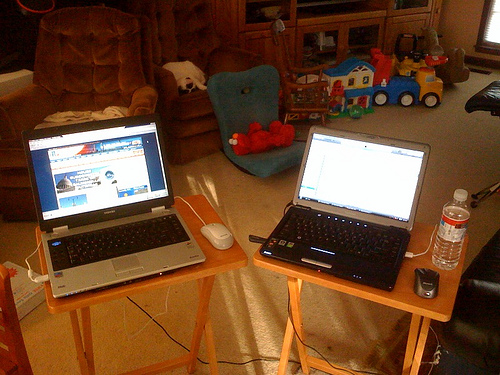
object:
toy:
[319, 45, 448, 120]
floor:
[1, 66, 500, 375]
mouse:
[200, 222, 235, 250]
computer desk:
[35, 194, 249, 374]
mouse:
[414, 268, 440, 299]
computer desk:
[252, 209, 470, 375]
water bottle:
[431, 188, 472, 270]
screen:
[21, 114, 175, 232]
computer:
[20, 113, 206, 298]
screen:
[292, 125, 429, 231]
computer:
[259, 125, 432, 292]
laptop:
[20, 112, 206, 299]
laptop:
[259, 126, 430, 293]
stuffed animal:
[228, 121, 294, 156]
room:
[0, 0, 499, 375]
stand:
[36, 194, 249, 374]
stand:
[251, 217, 470, 374]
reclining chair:
[0, 6, 159, 224]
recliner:
[140, 0, 265, 167]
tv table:
[252, 213, 475, 375]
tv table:
[24, 194, 249, 374]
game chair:
[206, 64, 307, 178]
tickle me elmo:
[228, 119, 296, 156]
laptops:
[22, 107, 432, 300]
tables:
[34, 194, 469, 375]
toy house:
[321, 57, 376, 119]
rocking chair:
[270, 18, 333, 128]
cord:
[173, 195, 207, 225]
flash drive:
[249, 235, 267, 244]